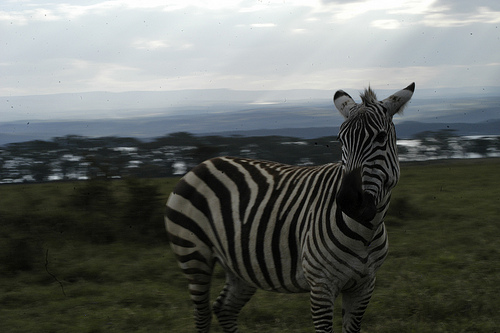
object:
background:
[2, 0, 497, 184]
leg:
[306, 277, 337, 332]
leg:
[341, 278, 378, 333]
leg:
[169, 237, 214, 332]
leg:
[211, 271, 257, 332]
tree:
[59, 179, 105, 216]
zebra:
[160, 80, 423, 333]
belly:
[216, 227, 312, 293]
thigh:
[167, 251, 224, 287]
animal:
[161, 79, 418, 332]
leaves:
[136, 188, 148, 193]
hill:
[0, 88, 282, 129]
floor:
[0, 181, 500, 333]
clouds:
[424, 0, 500, 50]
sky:
[0, 0, 500, 93]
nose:
[333, 179, 363, 206]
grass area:
[0, 167, 500, 333]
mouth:
[343, 200, 376, 221]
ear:
[332, 88, 360, 119]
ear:
[379, 81, 417, 114]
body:
[164, 155, 342, 292]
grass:
[1, 158, 499, 333]